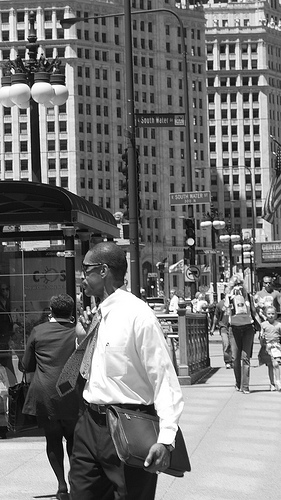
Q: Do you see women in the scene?
A: Yes, there is a woman.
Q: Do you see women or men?
A: Yes, there is a woman.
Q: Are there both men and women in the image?
A: Yes, there are both a woman and a man.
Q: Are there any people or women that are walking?
A: Yes, the woman is walking.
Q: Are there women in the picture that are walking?
A: Yes, there is a woman that is walking.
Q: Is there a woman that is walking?
A: Yes, there is a woman that is walking.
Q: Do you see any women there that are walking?
A: Yes, there is a woman that is walking.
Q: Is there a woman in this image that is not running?
A: Yes, there is a woman that is walking.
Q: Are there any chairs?
A: No, there are no chairs.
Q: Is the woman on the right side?
A: Yes, the woman is on the right of the image.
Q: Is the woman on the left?
A: No, the woman is on the right of the image.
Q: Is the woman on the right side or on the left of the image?
A: The woman is on the right of the image.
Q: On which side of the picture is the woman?
A: The woman is on the right of the image.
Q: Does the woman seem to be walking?
A: Yes, the woman is walking.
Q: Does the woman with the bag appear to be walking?
A: Yes, the woman is walking.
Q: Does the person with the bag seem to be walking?
A: Yes, the woman is walking.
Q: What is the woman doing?
A: The woman is walking.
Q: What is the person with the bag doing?
A: The woman is walking.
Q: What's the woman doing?
A: The woman is walking.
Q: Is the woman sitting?
A: No, the woman is walking.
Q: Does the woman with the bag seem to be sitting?
A: No, the woman is walking.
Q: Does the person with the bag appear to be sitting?
A: No, the woman is walking.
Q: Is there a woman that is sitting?
A: No, there is a woman but she is walking.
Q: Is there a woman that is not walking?
A: No, there is a woman but she is walking.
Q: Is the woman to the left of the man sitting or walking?
A: The woman is walking.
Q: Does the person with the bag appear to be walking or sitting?
A: The woman is walking.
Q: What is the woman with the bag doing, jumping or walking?
A: The woman is walking.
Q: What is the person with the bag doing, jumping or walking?
A: The woman is walking.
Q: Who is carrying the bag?
A: The woman is carrying the bag.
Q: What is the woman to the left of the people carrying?
A: The woman is carrying a bag.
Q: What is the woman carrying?
A: The woman is carrying a bag.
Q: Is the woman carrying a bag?
A: Yes, the woman is carrying a bag.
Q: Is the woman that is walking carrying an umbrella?
A: No, the woman is carrying a bag.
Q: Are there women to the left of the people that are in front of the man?
A: Yes, there is a woman to the left of the people.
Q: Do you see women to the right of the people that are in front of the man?
A: No, the woman is to the left of the people.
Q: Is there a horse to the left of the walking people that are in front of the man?
A: No, there is a woman to the left of the people.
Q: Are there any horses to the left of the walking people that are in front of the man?
A: No, there is a woman to the left of the people.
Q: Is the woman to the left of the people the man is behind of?
A: Yes, the woman is to the left of the people.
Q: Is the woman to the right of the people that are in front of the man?
A: No, the woman is to the left of the people.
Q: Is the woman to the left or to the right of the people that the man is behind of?
A: The woman is to the left of the people.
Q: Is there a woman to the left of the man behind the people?
A: Yes, there is a woman to the left of the man.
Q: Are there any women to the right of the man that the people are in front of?
A: No, the woman is to the left of the man.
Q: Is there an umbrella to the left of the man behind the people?
A: No, there is a woman to the left of the man.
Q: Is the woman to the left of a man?
A: Yes, the woman is to the left of a man.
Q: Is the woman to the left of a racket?
A: No, the woman is to the left of a man.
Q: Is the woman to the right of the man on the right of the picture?
A: No, the woman is to the left of the man.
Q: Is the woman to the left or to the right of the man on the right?
A: The woman is to the left of the man.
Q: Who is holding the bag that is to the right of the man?
A: The woman is holding the bag.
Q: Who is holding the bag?
A: The woman is holding the bag.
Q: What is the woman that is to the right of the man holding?
A: The woman is holding the bag.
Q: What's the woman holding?
A: The woman is holding the bag.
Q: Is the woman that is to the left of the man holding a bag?
A: Yes, the woman is holding a bag.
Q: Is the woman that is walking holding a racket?
A: No, the woman is holding a bag.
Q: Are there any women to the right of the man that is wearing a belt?
A: Yes, there is a woman to the right of the man.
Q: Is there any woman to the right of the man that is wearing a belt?
A: Yes, there is a woman to the right of the man.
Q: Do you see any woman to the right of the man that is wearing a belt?
A: Yes, there is a woman to the right of the man.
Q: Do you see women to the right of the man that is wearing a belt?
A: Yes, there is a woman to the right of the man.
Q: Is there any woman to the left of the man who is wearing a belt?
A: No, the woman is to the right of the man.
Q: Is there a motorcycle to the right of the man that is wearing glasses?
A: No, there is a woman to the right of the man.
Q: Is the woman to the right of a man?
A: Yes, the woman is to the right of a man.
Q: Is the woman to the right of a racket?
A: No, the woman is to the right of a man.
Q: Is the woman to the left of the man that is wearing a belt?
A: No, the woman is to the right of the man.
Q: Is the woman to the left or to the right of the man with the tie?
A: The woman is to the right of the man.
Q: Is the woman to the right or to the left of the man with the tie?
A: The woman is to the right of the man.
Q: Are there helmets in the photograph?
A: No, there are no helmets.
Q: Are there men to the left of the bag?
A: Yes, there is a man to the left of the bag.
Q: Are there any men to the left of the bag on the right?
A: Yes, there is a man to the left of the bag.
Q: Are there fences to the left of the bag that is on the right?
A: No, there is a man to the left of the bag.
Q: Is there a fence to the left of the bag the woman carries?
A: No, there is a man to the left of the bag.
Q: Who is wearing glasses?
A: The man is wearing glasses.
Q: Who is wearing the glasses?
A: The man is wearing glasses.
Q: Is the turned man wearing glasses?
A: Yes, the man is wearing glasses.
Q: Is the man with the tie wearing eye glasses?
A: No, the man is wearing glasses.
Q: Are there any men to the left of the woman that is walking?
A: Yes, there is a man to the left of the woman.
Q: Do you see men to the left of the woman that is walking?
A: Yes, there is a man to the left of the woman.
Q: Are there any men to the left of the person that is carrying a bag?
A: Yes, there is a man to the left of the woman.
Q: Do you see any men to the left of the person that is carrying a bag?
A: Yes, there is a man to the left of the woman.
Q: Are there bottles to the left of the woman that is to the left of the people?
A: No, there is a man to the left of the woman.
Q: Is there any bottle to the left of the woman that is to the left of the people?
A: No, there is a man to the left of the woman.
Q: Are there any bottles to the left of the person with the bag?
A: No, there is a man to the left of the woman.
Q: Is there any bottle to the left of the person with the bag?
A: No, there is a man to the left of the woman.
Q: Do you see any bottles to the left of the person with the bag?
A: No, there is a man to the left of the woman.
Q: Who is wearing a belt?
A: The man is wearing a belt.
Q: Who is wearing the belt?
A: The man is wearing a belt.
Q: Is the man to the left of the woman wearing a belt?
A: Yes, the man is wearing a belt.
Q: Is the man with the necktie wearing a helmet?
A: No, the man is wearing a belt.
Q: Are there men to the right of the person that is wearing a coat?
A: Yes, there is a man to the right of the person.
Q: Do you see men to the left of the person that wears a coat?
A: No, the man is to the right of the person.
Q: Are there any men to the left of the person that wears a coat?
A: No, the man is to the right of the person.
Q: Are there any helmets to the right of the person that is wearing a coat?
A: No, there is a man to the right of the person.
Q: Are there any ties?
A: Yes, there is a tie.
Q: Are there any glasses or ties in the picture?
A: Yes, there is a tie.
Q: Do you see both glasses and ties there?
A: Yes, there are both a tie and glasses.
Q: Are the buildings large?
A: Yes, the buildings are large.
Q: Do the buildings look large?
A: Yes, the buildings are large.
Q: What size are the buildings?
A: The buildings are large.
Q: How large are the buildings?
A: The buildings are large.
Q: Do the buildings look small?
A: No, the buildings are large.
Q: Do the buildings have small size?
A: No, the buildings are large.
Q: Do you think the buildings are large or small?
A: The buildings are large.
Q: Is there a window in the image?
A: Yes, there is a window.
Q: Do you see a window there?
A: Yes, there is a window.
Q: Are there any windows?
A: Yes, there is a window.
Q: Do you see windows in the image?
A: Yes, there is a window.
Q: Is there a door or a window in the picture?
A: Yes, there is a window.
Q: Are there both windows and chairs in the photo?
A: No, there is a window but no chairs.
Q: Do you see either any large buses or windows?
A: Yes, there is a large window.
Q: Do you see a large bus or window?
A: Yes, there is a large window.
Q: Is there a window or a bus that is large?
A: Yes, the window is large.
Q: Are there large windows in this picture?
A: Yes, there is a large window.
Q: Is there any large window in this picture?
A: Yes, there is a large window.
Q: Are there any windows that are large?
A: Yes, there is a window that is large.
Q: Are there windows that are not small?
A: Yes, there is a large window.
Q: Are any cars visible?
A: No, there are no cars.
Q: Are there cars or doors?
A: No, there are no cars or doors.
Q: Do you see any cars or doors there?
A: No, there are no cars or doors.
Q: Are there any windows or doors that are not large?
A: No, there is a window but it is large.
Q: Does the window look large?
A: Yes, the window is large.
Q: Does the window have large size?
A: Yes, the window is large.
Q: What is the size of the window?
A: The window is large.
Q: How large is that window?
A: The window is large.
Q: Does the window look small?
A: No, the window is large.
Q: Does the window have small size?
A: No, the window is large.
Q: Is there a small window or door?
A: No, there is a window but it is large.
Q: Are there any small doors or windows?
A: No, there is a window but it is large.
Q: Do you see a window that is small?
A: No, there is a window but it is large.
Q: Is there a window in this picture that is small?
A: No, there is a window but it is large.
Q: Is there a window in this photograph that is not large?
A: No, there is a window but it is large.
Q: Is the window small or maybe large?
A: The window is large.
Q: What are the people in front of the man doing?
A: The people are walking.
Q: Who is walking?
A: The people are walking.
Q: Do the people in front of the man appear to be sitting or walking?
A: The people are walking.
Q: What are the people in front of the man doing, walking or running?
A: The people are walking.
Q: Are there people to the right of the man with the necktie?
A: Yes, there are people to the right of the man.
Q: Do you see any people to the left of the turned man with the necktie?
A: No, the people are to the right of the man.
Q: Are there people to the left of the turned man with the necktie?
A: No, the people are to the right of the man.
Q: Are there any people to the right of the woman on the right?
A: Yes, there are people to the right of the woman.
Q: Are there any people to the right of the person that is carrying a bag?
A: Yes, there are people to the right of the woman.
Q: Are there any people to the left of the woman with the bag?
A: No, the people are to the right of the woman.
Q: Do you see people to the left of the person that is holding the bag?
A: No, the people are to the right of the woman.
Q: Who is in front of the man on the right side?
A: The people are in front of the man.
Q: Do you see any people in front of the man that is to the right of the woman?
A: Yes, there are people in front of the man.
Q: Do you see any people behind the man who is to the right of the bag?
A: No, the people are in front of the man.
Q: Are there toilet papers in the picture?
A: No, there are no toilet papers.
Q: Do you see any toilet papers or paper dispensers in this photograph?
A: No, there are no toilet papers or paper dispensers.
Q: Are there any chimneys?
A: No, there are no chimneys.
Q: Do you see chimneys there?
A: No, there are no chimneys.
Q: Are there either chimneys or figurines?
A: No, there are no chimneys or figurines.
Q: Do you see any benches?
A: No, there are no benches.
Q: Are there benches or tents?
A: No, there are no benches or tents.